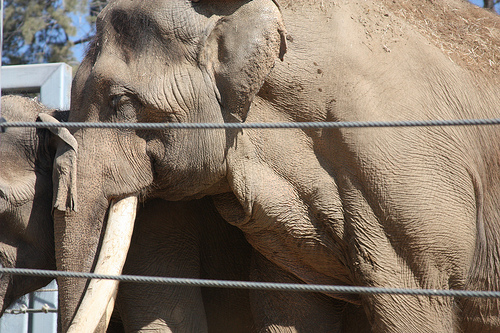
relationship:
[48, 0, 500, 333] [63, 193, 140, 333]
elephant has elephant tusk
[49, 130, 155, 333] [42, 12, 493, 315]
brown trunk of elephant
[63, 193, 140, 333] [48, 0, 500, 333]
elephant tusk on elephant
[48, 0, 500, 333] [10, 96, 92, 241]
elephant next to elephant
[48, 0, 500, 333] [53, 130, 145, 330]
elephant has brown trunk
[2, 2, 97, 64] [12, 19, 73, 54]
sky behind trees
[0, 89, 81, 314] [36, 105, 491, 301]
elephant in a fence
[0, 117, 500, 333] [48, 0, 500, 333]
elephant stockade in front of elephant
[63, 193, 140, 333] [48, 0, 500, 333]
elephant tusk of elephant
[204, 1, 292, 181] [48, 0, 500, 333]
ear of elephant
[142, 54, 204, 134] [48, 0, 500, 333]
wrinkle of elephant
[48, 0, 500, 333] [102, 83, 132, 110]
elephant with closed eye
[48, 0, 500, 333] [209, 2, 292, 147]
elephant has ear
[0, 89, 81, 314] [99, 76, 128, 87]
elephant has eyebrows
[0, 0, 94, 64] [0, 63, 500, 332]
trees outside pen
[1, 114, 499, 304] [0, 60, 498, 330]
retaining wire around elephant stockade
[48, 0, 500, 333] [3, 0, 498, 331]
elephant in pen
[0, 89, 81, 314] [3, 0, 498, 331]
elephant in pen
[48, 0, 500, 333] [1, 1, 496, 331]
elephant in enclosure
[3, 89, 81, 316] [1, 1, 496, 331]
elephant in enclosure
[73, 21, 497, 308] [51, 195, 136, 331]
elephant has tusk